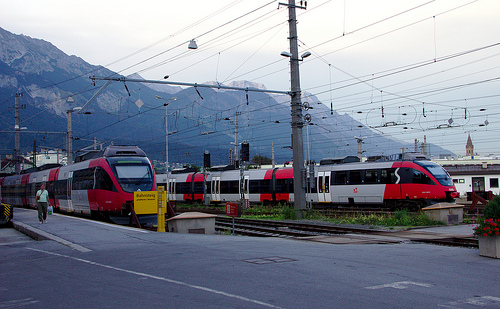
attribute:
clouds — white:
[80, 7, 380, 67]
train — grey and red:
[0, 140, 165, 228]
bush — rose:
[469, 194, 499, 260]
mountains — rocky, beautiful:
[3, 29, 455, 171]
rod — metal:
[102, 56, 296, 106]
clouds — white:
[361, 13, 462, 80]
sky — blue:
[333, 12, 472, 97]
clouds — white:
[2, 4, 197, 80]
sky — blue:
[2, 8, 497, 166]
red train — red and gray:
[155, 154, 461, 212]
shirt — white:
[35, 182, 50, 216]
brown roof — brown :
[162, 207, 221, 221]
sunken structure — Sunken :
[165, 209, 219, 234]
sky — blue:
[322, 11, 412, 69]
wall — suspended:
[0, 18, 273, 175]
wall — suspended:
[173, 78, 460, 167]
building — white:
[443, 153, 498, 197]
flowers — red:
[475, 214, 498, 234]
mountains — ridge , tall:
[1, 25, 454, 191]